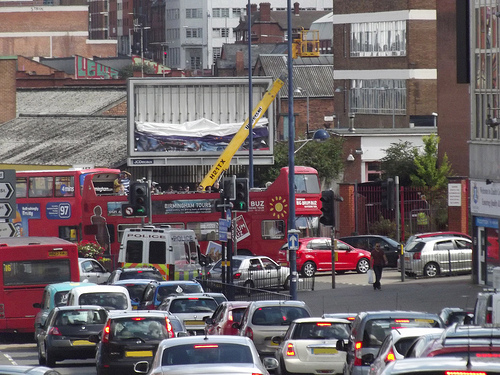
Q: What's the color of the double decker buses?
A: Red.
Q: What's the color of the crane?
A: Yellow.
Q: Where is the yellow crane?
A: Behind the red bus.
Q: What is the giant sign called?
A: Billboard.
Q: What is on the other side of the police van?
A: A big red bus.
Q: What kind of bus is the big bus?
A: Double decker.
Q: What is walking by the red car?
A: A person.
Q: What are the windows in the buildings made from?
A: Glass.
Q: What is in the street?
A: Traffic.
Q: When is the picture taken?
A: Daytime.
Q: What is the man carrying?
A: A white bag.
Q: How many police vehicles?
A: One.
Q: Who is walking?
A: A pedestrian.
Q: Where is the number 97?
A: On the side of the bus.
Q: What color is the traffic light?
A: Green.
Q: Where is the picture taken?
A: In a city.